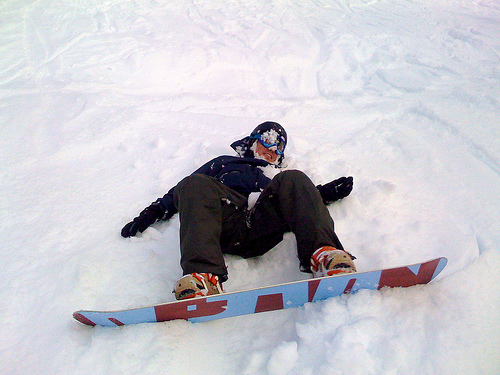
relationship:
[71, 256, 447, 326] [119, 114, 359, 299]
snowboard on man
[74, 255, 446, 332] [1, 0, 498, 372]
snowboard on snow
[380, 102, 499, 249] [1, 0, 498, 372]
track in snow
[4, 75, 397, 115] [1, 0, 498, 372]
track in snow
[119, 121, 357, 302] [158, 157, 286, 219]
man wearing jacket